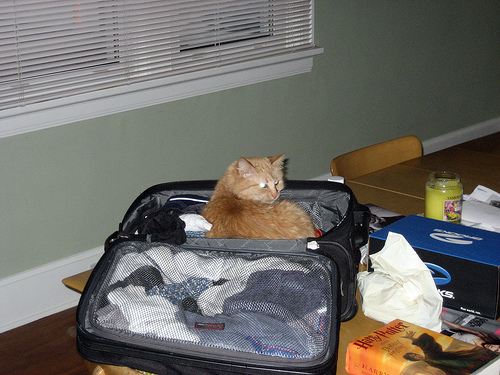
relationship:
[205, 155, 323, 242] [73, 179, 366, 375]
cat inside a case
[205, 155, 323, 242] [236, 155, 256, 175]
cat has an ear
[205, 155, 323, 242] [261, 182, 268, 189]
cat has an eye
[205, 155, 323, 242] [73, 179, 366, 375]
cat sitting in a case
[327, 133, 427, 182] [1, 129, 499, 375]
chair pushed into table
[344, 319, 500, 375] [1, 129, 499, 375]
book on table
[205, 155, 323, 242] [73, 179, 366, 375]
cat sitting inside a case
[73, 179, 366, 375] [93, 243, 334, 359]
case filled with clothes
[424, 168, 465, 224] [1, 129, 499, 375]
candle on table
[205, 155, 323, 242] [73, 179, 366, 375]
cat in case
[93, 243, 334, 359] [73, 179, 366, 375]
clothes are zippered in case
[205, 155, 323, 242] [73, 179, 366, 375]
cat laying in case